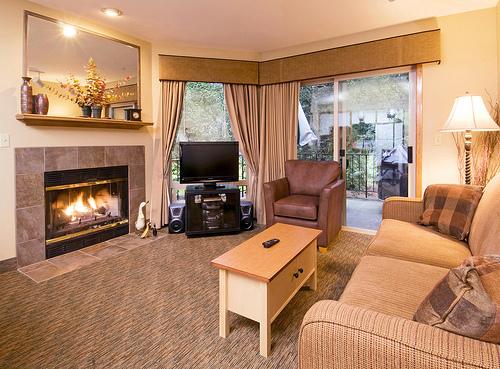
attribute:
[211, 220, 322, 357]
table — wooden, small, rectangular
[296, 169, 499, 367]
couch — brown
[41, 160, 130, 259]
fireplace — here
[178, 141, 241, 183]
tv — large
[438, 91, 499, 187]
lamp — ornate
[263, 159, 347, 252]
chair — brown, leather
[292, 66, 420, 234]
doors — sliding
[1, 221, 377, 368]
floor — speckled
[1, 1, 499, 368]
room — neat, here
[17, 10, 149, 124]
mirror — large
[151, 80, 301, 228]
draperies — open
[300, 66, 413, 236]
door — glass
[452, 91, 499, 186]
grasses — dried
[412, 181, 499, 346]
pillows — plaid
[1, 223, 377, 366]
carpeting — wall-to-wall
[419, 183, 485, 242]
pillow — plaid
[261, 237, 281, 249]
remote — black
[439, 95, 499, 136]
shade — white